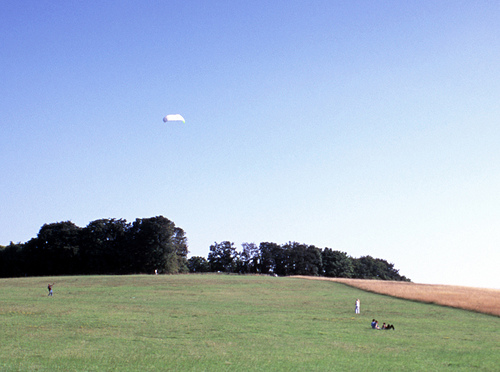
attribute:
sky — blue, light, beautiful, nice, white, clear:
[238, 42, 273, 65]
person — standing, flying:
[351, 293, 367, 316]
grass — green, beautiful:
[327, 313, 361, 341]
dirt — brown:
[420, 281, 445, 299]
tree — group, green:
[31, 228, 273, 270]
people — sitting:
[339, 307, 407, 354]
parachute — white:
[142, 103, 191, 152]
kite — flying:
[162, 99, 198, 139]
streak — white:
[294, 130, 456, 195]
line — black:
[419, 295, 463, 308]